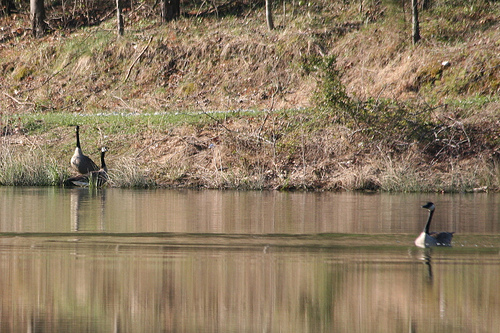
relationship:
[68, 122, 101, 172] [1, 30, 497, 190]
goose on land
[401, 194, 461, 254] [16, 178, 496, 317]
bird inside of water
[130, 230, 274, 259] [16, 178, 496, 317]
ripples are on top of water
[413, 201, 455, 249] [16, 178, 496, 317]
bird are inside of water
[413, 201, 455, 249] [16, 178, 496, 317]
bird inside of water